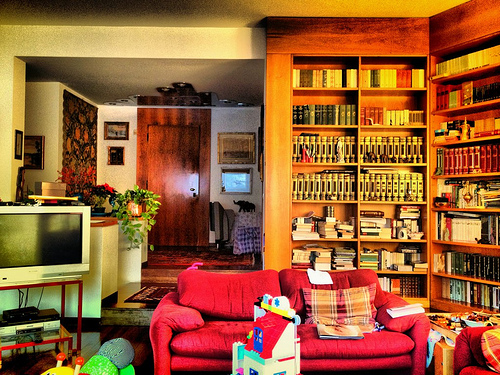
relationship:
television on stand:
[0, 204, 92, 286] [1, 282, 84, 365]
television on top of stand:
[0, 204, 92, 286] [1, 282, 84, 365]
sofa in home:
[150, 269, 430, 373] [1, 2, 497, 372]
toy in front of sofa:
[234, 292, 300, 374] [150, 269, 430, 373]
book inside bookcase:
[300, 70, 304, 86] [263, 2, 498, 314]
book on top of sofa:
[387, 299, 425, 320] [150, 269, 430, 373]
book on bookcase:
[300, 70, 304, 86] [263, 2, 498, 314]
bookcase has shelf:
[263, 2, 498, 314] [293, 88, 357, 93]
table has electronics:
[0, 322, 73, 366] [2, 307, 60, 333]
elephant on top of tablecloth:
[235, 200, 257, 213] [234, 212, 261, 252]